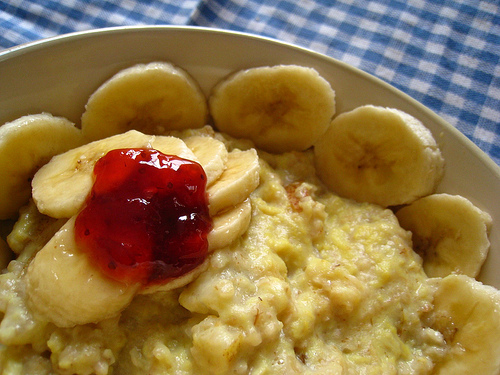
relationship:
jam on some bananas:
[66, 153, 226, 281] [25, 129, 262, 326]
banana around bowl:
[307, 102, 447, 210] [4, 27, 496, 373]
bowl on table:
[4, 27, 496, 373] [2, 0, 491, 359]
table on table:
[0, 0, 500, 375] [6, 24, 498, 374]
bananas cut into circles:
[1, 114, 82, 182] [227, 61, 337, 157]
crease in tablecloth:
[183, 1, 217, 28] [2, 2, 496, 178]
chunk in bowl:
[0, 124, 449, 375] [4, 27, 496, 373]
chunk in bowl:
[0, 124, 449, 375] [160, 20, 341, 54]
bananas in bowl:
[7, 67, 332, 325] [4, 27, 496, 373]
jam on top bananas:
[73, 146, 212, 288] [25, 129, 262, 326]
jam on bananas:
[73, 146, 212, 288] [207, 199, 254, 255]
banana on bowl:
[315, 104, 446, 207] [41, 44, 91, 77]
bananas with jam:
[13, 52, 292, 327] [73, 146, 212, 288]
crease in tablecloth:
[144, 7, 251, 31] [383, 10, 482, 73]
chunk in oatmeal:
[203, 283, 246, 355] [255, 228, 442, 370]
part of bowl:
[448, 135, 475, 174] [4, 27, 496, 373]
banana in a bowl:
[306, 97, 446, 217] [4, 27, 496, 373]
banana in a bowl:
[432, 271, 499, 373] [0, 25, 500, 282]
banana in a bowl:
[212, 49, 333, 164] [4, 27, 496, 373]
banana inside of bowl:
[25, 242, 80, 324] [3, 27, 488, 218]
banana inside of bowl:
[315, 104, 446, 207] [0, 25, 500, 282]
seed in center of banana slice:
[265, 96, 283, 109] [195, 40, 376, 146]